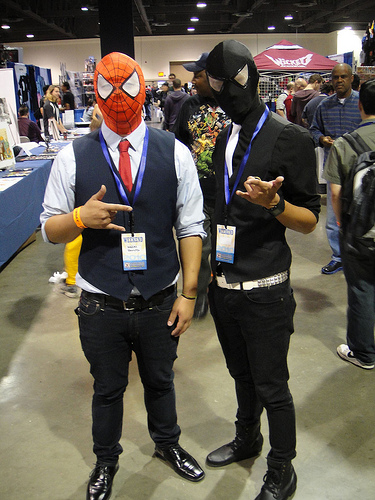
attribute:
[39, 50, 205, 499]
man — standing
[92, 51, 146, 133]
mask — red, orange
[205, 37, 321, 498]
man — standing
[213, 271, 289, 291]
belt — white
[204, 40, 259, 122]
mask — black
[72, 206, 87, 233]
wristband — yellow, orange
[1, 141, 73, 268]
table cloth — blue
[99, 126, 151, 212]
lanyard — blue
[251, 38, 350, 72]
tent — red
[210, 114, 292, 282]
vest — black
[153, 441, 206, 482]
shoe — black, shiny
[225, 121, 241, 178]
tie — white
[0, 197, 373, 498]
sidewalk — grey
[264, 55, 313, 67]
logo — white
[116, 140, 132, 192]
tie — red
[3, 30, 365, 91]
wall — white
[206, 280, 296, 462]
pants — black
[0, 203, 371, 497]
floor — here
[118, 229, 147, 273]
tag — here, blue, white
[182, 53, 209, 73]
cap — here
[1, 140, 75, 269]
table — here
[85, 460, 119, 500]
shoe — here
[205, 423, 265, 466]
boot — black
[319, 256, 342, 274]
shoe — blue, black